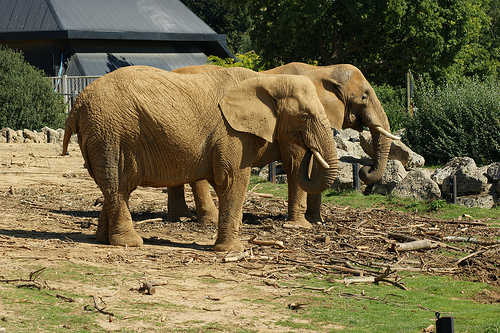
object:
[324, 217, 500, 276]
branches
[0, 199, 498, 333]
ground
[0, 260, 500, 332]
grass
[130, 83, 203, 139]
skin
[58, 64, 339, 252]
elephants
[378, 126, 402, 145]
tusks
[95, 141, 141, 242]
leg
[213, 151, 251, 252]
leg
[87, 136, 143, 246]
leg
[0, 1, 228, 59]
roof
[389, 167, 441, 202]
rocks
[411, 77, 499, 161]
bush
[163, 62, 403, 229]
elephant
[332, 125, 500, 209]
pile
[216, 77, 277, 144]
ear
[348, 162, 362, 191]
post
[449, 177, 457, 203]
post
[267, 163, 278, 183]
post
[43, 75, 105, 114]
fence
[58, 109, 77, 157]
tail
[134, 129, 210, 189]
stomach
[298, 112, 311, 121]
eye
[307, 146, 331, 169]
tusk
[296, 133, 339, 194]
trunk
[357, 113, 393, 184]
trunk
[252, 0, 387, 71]
trees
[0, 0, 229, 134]
building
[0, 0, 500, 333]
day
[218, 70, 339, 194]
head